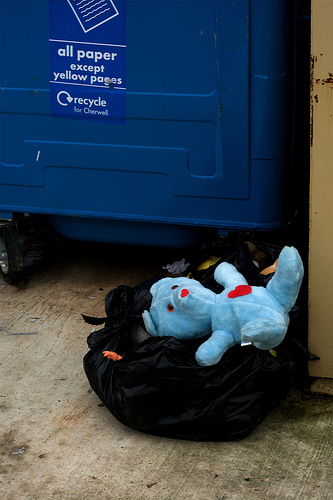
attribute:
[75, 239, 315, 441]
bag — plastic, black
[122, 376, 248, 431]
bag — black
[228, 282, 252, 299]
heart — red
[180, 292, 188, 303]
heart nose — red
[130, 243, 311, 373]
plushie — sky blue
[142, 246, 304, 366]
teddy — blue